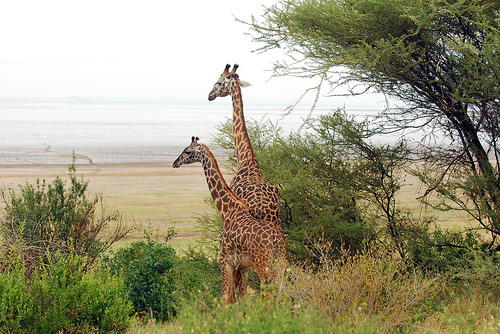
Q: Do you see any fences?
A: No, there are no fences.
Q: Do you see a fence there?
A: No, there are no fences.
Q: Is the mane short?
A: Yes, the mane is short.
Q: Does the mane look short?
A: Yes, the mane is short.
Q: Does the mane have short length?
A: Yes, the mane is short.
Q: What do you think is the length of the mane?
A: The mane is short.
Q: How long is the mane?
A: The mane is short.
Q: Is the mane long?
A: No, the mane is short.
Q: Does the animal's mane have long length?
A: No, the mane is short.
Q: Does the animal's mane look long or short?
A: The mane is short.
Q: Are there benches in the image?
A: No, there are no benches.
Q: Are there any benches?
A: No, there are no benches.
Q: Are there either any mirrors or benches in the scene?
A: No, there are no benches or mirrors.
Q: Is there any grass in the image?
A: Yes, there is grass.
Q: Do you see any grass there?
A: Yes, there is grass.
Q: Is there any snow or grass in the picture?
A: Yes, there is grass.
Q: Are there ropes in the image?
A: No, there are no ropes.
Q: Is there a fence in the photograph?
A: No, there are no fences.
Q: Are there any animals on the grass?
A: Yes, there is an animal on the grass.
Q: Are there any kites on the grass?
A: No, there is an animal on the grass.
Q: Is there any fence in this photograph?
A: No, there are no fences.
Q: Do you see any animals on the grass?
A: Yes, there is an animal on the grass.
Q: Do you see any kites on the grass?
A: No, there is an animal on the grass.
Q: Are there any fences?
A: No, there are no fences.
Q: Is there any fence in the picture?
A: No, there are no fences.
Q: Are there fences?
A: No, there are no fences.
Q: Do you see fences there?
A: No, there are no fences.